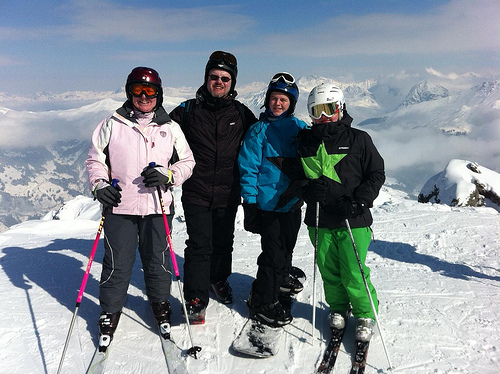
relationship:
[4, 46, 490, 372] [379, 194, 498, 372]
top of ski slope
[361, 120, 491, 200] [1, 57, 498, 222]
clouds in mountains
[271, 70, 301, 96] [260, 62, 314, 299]
helmet of girl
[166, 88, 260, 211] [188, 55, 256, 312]
ski jacket of man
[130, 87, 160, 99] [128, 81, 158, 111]
goggles on face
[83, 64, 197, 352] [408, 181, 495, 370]
person on mountain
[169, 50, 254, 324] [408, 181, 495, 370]
man on mountain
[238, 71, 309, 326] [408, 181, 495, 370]
girl on mountain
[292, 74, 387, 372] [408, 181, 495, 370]
skier on mountain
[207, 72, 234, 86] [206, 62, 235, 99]
sunglasses on face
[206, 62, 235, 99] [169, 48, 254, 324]
face of man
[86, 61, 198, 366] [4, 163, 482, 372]
person on ski slope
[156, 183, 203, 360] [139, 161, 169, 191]
ski pole in hand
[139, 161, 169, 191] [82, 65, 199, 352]
hand of skier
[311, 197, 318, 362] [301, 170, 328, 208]
ski pole in hand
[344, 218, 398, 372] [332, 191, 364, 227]
ski pole in hand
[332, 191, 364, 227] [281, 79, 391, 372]
hand of skier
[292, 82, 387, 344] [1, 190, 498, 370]
skier on hillside